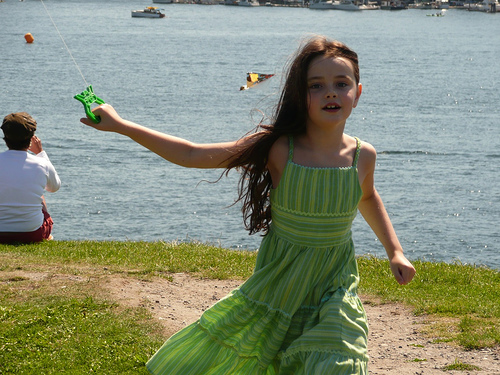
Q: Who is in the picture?
A: Little girl.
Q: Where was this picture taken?
A: By water.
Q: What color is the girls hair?
A: Brown.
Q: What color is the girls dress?
A: Green.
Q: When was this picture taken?
A: Daytime.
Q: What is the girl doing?
A: Flying kite.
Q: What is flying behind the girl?
A: Kite.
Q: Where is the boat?
A: In the water.